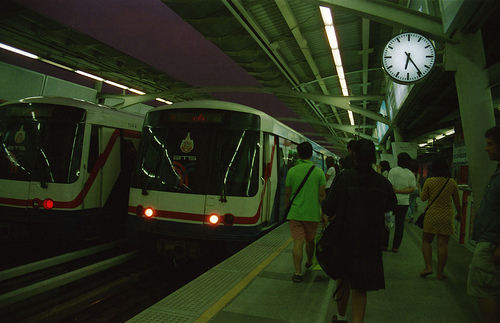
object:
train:
[121, 98, 336, 239]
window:
[147, 107, 255, 192]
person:
[413, 156, 463, 281]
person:
[326, 139, 399, 316]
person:
[281, 137, 323, 288]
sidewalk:
[125, 209, 494, 316]